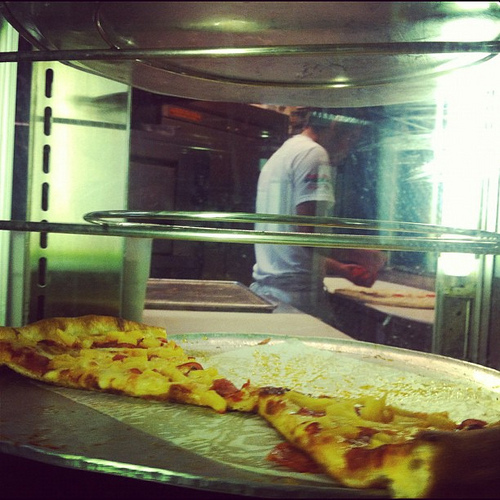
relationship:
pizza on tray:
[251, 376, 500, 499] [1, 327, 500, 498]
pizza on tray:
[1, 309, 260, 417] [1, 327, 500, 498]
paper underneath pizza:
[29, 335, 500, 493] [251, 376, 500, 499]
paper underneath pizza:
[29, 335, 500, 493] [1, 309, 260, 417]